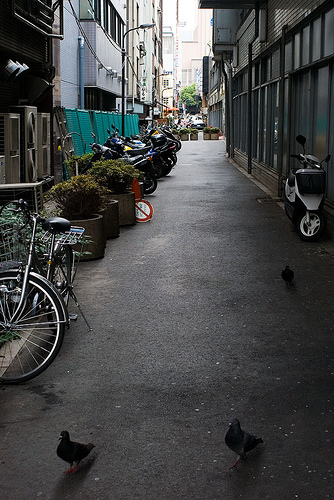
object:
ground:
[50, 404, 330, 489]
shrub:
[85, 159, 131, 200]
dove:
[276, 260, 304, 287]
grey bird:
[223, 417, 264, 470]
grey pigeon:
[52, 429, 96, 474]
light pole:
[120, 14, 156, 135]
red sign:
[132, 197, 153, 223]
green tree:
[178, 83, 202, 117]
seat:
[42, 216, 72, 234]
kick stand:
[69, 288, 94, 334]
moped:
[278, 132, 332, 243]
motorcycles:
[87, 114, 183, 195]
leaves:
[191, 85, 199, 93]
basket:
[0, 223, 27, 267]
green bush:
[50, 167, 106, 222]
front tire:
[297, 212, 325, 243]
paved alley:
[169, 128, 270, 412]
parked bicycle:
[2, 214, 97, 378]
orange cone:
[127, 169, 142, 205]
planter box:
[211, 125, 220, 141]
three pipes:
[5, 58, 34, 86]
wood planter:
[80, 189, 136, 256]